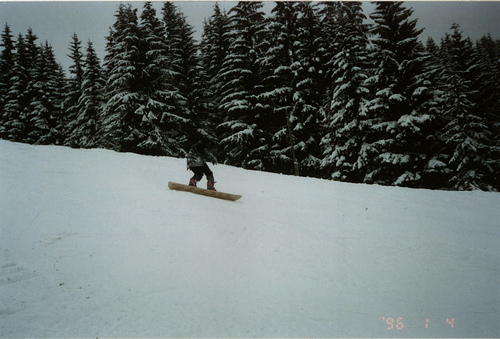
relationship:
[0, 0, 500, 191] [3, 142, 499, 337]
pine covered in snow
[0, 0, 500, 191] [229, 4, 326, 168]
pine covered in snow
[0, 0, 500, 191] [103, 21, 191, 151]
pine covered in snow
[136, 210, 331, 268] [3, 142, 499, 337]
ski mark in snow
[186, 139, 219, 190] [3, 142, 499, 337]
person in snow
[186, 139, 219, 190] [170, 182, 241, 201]
person has snowboard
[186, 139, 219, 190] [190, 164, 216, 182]
person wearing black pants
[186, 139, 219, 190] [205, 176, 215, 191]
person has snow boot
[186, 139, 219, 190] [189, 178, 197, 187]
person has boot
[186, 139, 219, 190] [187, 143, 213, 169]
person wearing coat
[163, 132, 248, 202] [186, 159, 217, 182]
skier wears black pants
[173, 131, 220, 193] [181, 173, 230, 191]
snow boarder wearing boots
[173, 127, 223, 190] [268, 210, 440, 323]
boarder covered in snow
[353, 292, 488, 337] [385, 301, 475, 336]
numbers printed on photograph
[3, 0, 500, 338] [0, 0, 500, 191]
snow covered pine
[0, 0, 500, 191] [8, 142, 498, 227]
pine on side of snow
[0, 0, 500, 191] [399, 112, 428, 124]
pine covered with snow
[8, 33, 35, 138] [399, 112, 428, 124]
pine covered with snow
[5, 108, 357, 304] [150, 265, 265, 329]
hill covered with snow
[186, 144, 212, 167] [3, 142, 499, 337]
coat dusted with snow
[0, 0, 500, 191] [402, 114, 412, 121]
pine have snow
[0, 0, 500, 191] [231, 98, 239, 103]
pine have snow